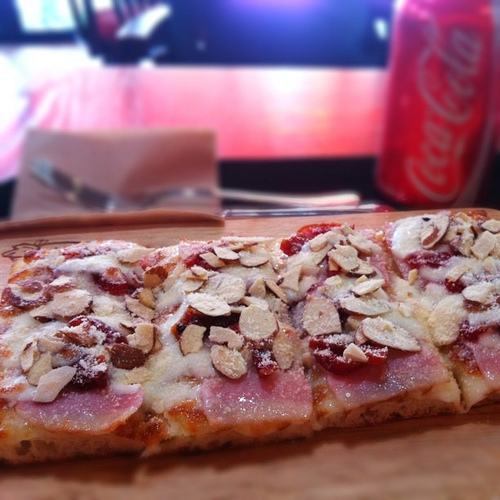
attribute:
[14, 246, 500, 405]
pizza — square, red, sliced, fresh, long, toasted, on table, covered, sqaure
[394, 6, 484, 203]
coke — red, blurry, far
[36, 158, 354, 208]
fork — silver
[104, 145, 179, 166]
napkin — brown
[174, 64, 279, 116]
table — far, red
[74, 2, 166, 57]
chair — black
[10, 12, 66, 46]
door — hard to see